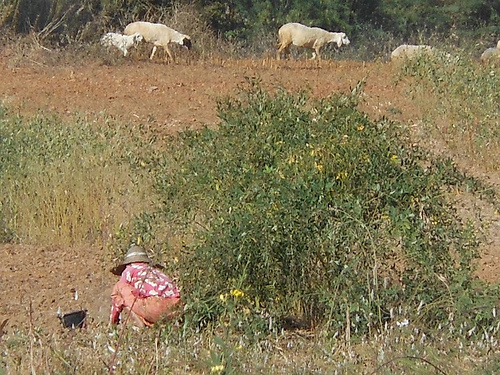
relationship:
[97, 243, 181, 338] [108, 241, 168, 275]
woman has hat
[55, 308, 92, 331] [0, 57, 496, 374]
bucket sitting on ground